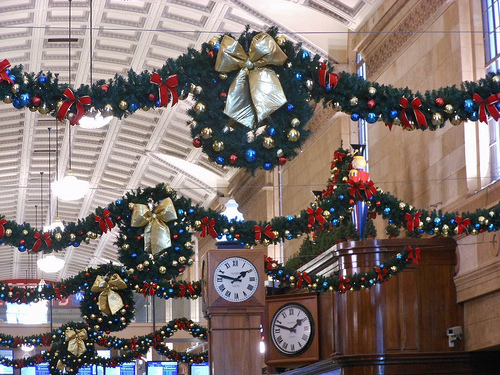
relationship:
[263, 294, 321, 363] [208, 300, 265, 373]
clock on wall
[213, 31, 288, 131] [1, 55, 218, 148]
bow on wreath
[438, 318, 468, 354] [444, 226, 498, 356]
camera against wall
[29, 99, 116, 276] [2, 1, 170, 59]
lights on ceiling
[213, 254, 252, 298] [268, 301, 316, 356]
numbers on clock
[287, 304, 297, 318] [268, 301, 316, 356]
roman numerals on clock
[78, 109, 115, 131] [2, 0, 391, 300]
light hanging from ceiling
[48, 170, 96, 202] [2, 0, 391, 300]
light hanging from ceiling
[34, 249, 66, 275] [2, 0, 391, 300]
light hanging from ceiling